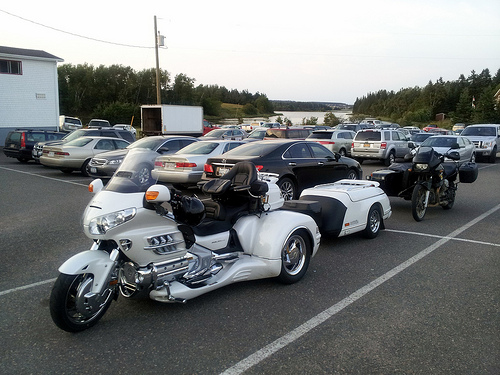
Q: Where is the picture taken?
A: A parking lot.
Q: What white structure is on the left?
A: A building.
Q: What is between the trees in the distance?
A: Water.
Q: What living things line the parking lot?
A: Trees.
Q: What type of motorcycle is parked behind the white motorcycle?
A: A black one.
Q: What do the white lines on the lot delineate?
A: Parking spaces.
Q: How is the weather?
A: Clear.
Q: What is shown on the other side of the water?
A: Hills.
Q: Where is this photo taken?
A: Parking lot.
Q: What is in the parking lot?
A: Vehicles.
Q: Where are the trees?
A: Behind the cars.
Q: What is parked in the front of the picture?
A: Motorcycle.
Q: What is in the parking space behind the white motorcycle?
A: Black motorcycle.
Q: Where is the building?
A: At the edge of the parking lot.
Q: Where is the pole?
A: In front of the trees.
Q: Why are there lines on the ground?
A: To separate the parking spaces.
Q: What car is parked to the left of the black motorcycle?
A: Black sedan.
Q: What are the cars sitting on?
A: Pavement.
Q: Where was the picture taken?
A: In a parking lot.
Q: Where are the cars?
A: In the parking lot.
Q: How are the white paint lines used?
A: To indicate a parking space.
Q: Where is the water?
A: On the other side of the parking lot.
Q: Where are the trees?
A: In the distance.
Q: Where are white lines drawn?
A: On the asphalt.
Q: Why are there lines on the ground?
A: To show parking spots.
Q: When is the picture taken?
A: Daytime.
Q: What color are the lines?
A: White.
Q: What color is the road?
A: Gray.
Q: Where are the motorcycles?
A: In parking spots.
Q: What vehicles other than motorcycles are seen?
A: Cars.